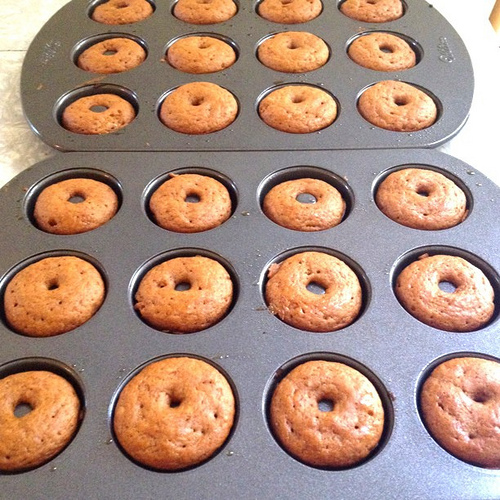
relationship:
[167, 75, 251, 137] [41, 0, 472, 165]
muffin in pan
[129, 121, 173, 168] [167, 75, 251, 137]
crumb of muffin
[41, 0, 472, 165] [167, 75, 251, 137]
pan of muffin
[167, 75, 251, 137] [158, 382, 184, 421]
muffin with chocolate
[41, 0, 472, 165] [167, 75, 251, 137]
pan for muffin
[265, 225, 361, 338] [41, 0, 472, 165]
cookie in pan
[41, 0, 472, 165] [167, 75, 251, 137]
pan for doughnut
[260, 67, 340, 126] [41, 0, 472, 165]
doughnut in pan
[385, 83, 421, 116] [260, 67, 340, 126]
hole in doughnut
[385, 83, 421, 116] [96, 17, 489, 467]
hole in goods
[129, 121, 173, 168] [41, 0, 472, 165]
crumb on pan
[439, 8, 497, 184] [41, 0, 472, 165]
table under pan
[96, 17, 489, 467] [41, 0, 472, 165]
goods in pan